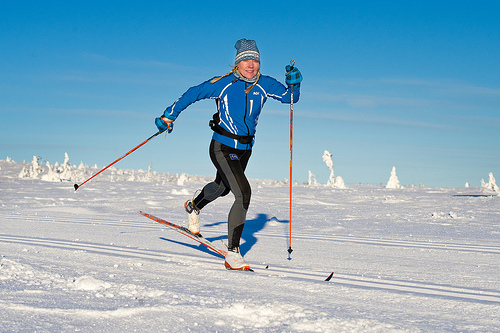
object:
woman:
[153, 35, 302, 271]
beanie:
[232, 38, 259, 65]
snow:
[0, 149, 499, 333]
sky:
[0, 0, 496, 188]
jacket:
[162, 72, 303, 151]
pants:
[179, 141, 253, 250]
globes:
[288, 245, 292, 253]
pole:
[287, 86, 294, 253]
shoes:
[223, 250, 252, 271]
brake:
[134, 206, 335, 282]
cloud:
[0, 78, 499, 188]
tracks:
[0, 233, 499, 307]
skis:
[130, 208, 335, 304]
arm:
[160, 76, 215, 120]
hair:
[228, 63, 261, 70]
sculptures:
[38, 159, 63, 182]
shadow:
[158, 212, 291, 265]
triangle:
[380, 166, 407, 190]